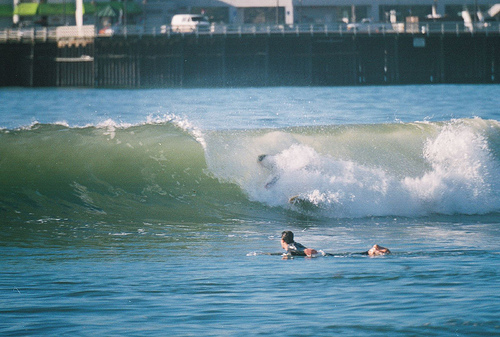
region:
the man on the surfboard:
[255, 225, 398, 263]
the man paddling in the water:
[257, 225, 398, 265]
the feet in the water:
[366, 240, 394, 262]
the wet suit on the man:
[277, 243, 371, 263]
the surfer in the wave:
[251, 145, 313, 191]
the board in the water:
[287, 188, 339, 216]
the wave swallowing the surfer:
[8, 108, 498, 217]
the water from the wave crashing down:
[314, 129, 498, 214]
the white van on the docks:
[166, 8, 211, 33]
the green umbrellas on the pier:
[3, 0, 138, 17]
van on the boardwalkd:
[158, 5, 215, 47]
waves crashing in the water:
[138, 107, 396, 219]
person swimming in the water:
[253, 216, 424, 276]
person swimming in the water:
[238, 152, 363, 217]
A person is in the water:
[10, 110, 485, 315]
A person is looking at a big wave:
[30, 86, 468, 317]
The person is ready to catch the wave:
[16, 111, 466, 321]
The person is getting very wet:
[25, 121, 476, 334]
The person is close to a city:
[36, 95, 481, 290]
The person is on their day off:
[41, 115, 472, 335]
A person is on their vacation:
[55, 105, 465, 320]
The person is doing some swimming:
[26, 107, 486, 322]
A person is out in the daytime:
[31, 102, 467, 297]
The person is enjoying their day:
[44, 121, 466, 316]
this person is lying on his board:
[209, 221, 455, 276]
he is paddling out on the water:
[227, 200, 493, 272]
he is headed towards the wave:
[208, 216, 409, 274]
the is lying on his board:
[213, 205, 411, 270]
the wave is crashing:
[112, 88, 492, 221]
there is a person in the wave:
[242, 140, 329, 215]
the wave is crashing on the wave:
[197, 106, 357, 235]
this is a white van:
[151, 11, 217, 38]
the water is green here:
[8, 123, 496, 230]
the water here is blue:
[2, 241, 491, 331]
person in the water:
[241, 222, 395, 269]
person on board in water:
[249, 149, 351, 221]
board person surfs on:
[288, 191, 350, 218]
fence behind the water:
[18, 32, 498, 81]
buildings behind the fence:
[13, 4, 461, 27]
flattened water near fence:
[18, 88, 391, 107]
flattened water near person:
[7, 263, 474, 320]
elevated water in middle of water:
[3, 98, 495, 225]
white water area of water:
[288, 138, 468, 198]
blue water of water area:
[34, 278, 373, 335]